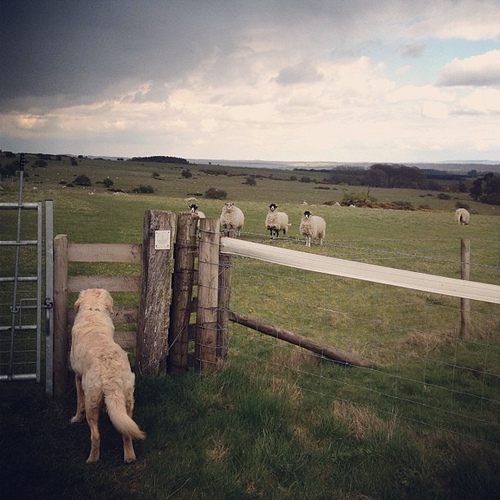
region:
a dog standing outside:
[24, 169, 265, 489]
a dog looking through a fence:
[14, 216, 256, 498]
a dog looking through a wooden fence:
[36, 257, 196, 471]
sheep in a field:
[148, 128, 460, 308]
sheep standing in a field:
[146, 154, 481, 359]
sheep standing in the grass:
[135, 145, 447, 305]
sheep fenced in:
[82, 136, 415, 412]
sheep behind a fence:
[84, 145, 447, 400]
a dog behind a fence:
[24, 213, 300, 498]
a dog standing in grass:
[25, 259, 193, 494]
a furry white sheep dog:
[67, 289, 145, 466]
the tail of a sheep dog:
[99, 375, 149, 439]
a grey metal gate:
[0, 172, 56, 397]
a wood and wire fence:
[53, 209, 498, 445]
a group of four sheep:
[189, 202, 322, 247]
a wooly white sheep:
[297, 211, 329, 247]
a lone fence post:
[460, 240, 474, 344]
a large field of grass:
[1, 150, 499, 499]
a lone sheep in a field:
[452, 207, 472, 227]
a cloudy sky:
[0, 2, 499, 162]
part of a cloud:
[261, 44, 301, 91]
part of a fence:
[363, 294, 398, 329]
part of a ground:
[304, 363, 336, 402]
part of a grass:
[263, 424, 298, 454]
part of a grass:
[244, 450, 279, 496]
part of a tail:
[114, 403, 160, 433]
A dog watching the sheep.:
[78, 286, 146, 439]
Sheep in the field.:
[190, 191, 339, 253]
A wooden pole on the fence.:
[150, 208, 182, 385]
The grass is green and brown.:
[199, 367, 353, 448]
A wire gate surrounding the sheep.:
[220, 213, 420, 403]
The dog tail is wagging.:
[97, 380, 149, 430]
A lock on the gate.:
[10, 285, 67, 327]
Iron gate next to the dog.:
[13, 184, 73, 404]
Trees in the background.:
[110, 141, 373, 206]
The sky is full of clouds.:
[88, 43, 340, 145]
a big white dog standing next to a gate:
[57, 206, 155, 478]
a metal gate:
[0, 188, 60, 406]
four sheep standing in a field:
[165, 189, 352, 230]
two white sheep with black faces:
[260, 201, 342, 238]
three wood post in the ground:
[138, 203, 228, 388]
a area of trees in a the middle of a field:
[309, 162, 459, 197]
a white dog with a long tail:
[71, 264, 171, 446]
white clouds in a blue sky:
[267, 25, 479, 136]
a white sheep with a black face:
[295, 188, 329, 255]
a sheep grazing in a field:
[451, 191, 476, 236]